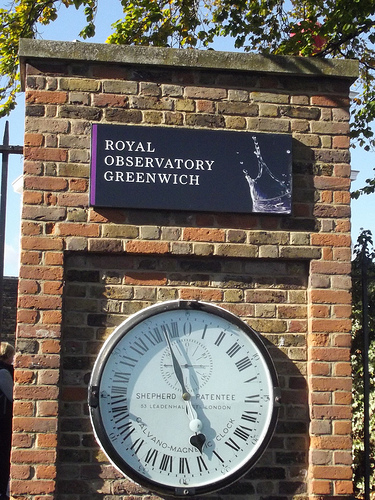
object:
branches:
[150, 0, 273, 45]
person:
[1, 338, 18, 500]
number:
[107, 318, 262, 479]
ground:
[233, 160, 258, 187]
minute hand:
[163, 325, 190, 399]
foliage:
[121, 0, 337, 57]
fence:
[349, 277, 374, 479]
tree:
[0, 0, 375, 258]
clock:
[88, 296, 280, 496]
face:
[80, 292, 302, 497]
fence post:
[0, 119, 30, 342]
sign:
[89, 121, 293, 214]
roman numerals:
[193, 317, 233, 349]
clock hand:
[185, 397, 206, 458]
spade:
[190, 433, 206, 454]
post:
[329, 228, 368, 313]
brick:
[113, 81, 269, 113]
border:
[87, 297, 281, 500]